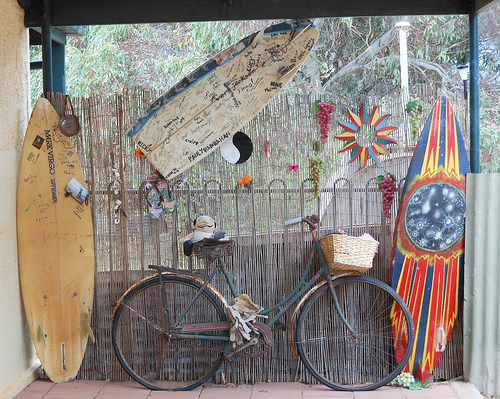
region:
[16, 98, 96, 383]
tan wood surf board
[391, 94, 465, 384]
blue red and yellow surf board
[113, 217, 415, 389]
blue metal bike on ground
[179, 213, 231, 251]
stuffed toy on bike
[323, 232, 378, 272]
brown wicker basket on bike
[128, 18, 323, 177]
blue and white surf board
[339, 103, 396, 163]
blue red and yellow plaque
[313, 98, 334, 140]
red plastic grapes on wall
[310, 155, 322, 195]
green plastic grapes on wall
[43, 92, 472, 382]
brown grass fence panel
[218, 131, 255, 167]
black and white yin yang symbol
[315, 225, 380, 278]
basket on front of the bike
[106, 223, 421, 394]
old rusty bike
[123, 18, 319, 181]
surfboard covered with signatures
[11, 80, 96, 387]
surfboard with writing on it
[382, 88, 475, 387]
surfboard with a circular pattern in the middle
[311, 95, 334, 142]
bunch of red grapes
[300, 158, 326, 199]
bunch of green grapes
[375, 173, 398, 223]
red grapes on the fence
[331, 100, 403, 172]
blue red and yellow sun pattern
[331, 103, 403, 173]
sunburst with red yellow blue points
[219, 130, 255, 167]
round disk with ying and yang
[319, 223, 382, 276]
white weave basket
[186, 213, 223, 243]
stuffed doll with black handlebar moustache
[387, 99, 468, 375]
boggy board with flame stripes red yellow and blue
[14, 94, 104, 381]
brown boggy board with words written on it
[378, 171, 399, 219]
bunch of red grapes hanging on the fence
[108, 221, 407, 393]
bicycle parked against the wall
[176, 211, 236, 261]
man doll sitting on the bicycle seat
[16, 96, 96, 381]
Tan surf board with writing on it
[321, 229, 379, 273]
Basket on front of bicycle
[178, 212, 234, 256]
Stuffed toy sitting on bicycle seat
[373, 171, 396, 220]
Artificial purple grapes on fence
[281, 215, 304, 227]
Gray bicycle handle on bike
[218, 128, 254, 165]
Yin yang symbol on fence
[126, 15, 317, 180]
Autographed blue and tan surf board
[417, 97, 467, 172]
Yellow blue and red design on surf board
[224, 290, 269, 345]
Large tan cloth gloves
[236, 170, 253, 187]
Orange flower sitting on fence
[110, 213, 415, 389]
A blue bicycle parked at the railing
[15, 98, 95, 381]
Brown wooden surfboard kept vertical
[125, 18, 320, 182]
A white surfboard with blue edge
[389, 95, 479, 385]
A blue surfboard with red and yellow stripes and a grey circle in the center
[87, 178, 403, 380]
A railing of metal pipes and rods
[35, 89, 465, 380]
Straw fence along the railing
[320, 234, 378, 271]
Carry basket on the bicycle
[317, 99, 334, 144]
A bunch of red grapes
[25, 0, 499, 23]
Ceiling of the balcony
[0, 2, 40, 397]
yellow wall of the balcony